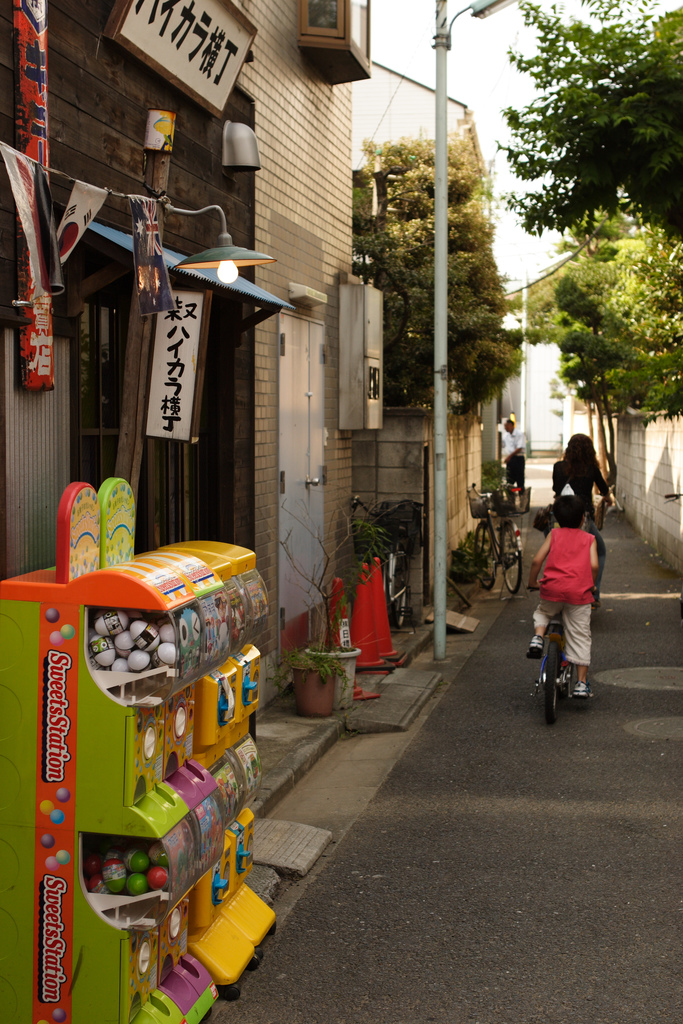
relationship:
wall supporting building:
[232, 1, 354, 723] [2, 2, 373, 727]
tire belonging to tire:
[545, 639, 559, 723] [537, 629, 565, 725]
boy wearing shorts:
[522, 490, 603, 698] [527, 594, 595, 669]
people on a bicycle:
[505, 409, 639, 781] [531, 613, 572, 724]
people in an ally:
[525, 435, 615, 723] [386, 519, 681, 975]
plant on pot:
[282, 519, 350, 649] [295, 643, 362, 722]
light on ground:
[599, 583, 682, 605] [601, 537, 681, 659]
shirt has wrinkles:
[537, 524, 601, 608] [539, 559, 570, 590]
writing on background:
[39, 643, 71, 784] [33, 604, 76, 1017]